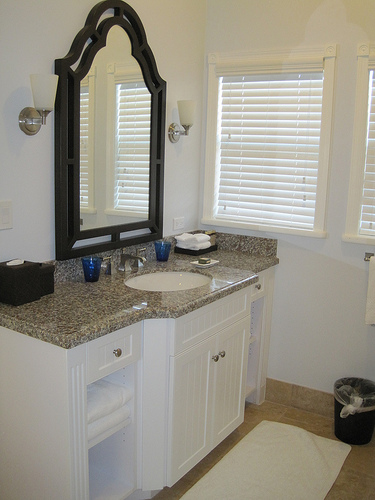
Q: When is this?
A: Daytime.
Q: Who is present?
A: No one.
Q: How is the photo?
A: Clear.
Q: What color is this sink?
A: White.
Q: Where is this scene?
A: In a bathroom.